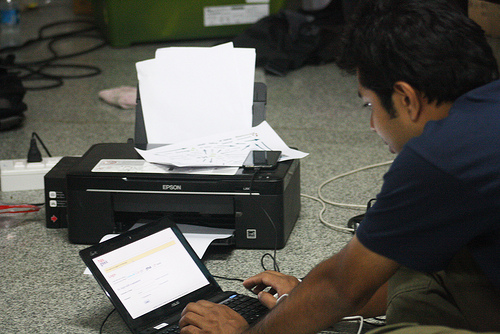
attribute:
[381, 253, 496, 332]
pants — gray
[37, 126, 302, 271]
printer — black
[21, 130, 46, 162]
power cord — black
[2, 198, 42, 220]
strip — beige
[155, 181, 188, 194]
writing — white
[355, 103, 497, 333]
shirt — blue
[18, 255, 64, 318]
carpet — grey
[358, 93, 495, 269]
shirt — blue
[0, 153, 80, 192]
strip — white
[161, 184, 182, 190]
logo — manufacturer brand